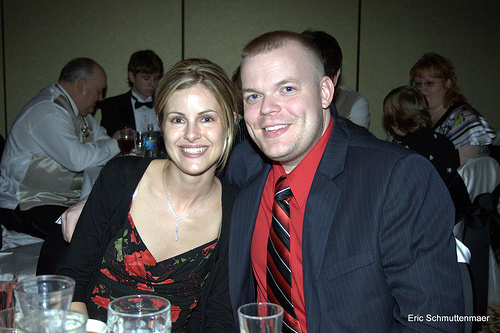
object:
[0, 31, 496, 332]
people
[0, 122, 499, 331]
banquet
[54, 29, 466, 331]
man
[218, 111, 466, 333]
clothes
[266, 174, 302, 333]
tie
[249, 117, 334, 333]
shirt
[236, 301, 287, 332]
flute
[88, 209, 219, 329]
dress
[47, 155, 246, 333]
sweater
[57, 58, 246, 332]
woman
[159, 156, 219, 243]
necklace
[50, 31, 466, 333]
couple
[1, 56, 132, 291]
man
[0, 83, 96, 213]
vest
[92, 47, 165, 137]
boy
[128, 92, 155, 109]
bowtie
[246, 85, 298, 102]
eyes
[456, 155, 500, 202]
cover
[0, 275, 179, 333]
glasses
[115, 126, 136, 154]
glass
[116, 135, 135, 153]
wine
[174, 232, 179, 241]
diamond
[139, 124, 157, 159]
bottle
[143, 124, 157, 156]
water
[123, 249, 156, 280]
rose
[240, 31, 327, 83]
hair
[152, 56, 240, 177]
hair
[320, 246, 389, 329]
pocket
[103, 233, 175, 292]
flowers